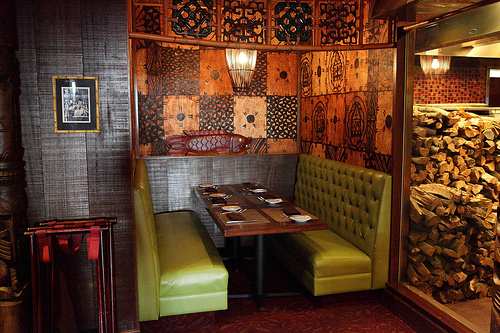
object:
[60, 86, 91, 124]
picture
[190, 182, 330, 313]
table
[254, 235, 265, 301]
pole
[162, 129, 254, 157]
fish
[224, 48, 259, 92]
light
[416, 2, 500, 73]
ceiling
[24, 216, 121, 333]
basket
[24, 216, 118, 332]
tray holder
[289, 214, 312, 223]
plate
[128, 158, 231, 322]
bench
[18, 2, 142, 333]
wall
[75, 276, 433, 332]
floor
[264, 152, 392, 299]
benches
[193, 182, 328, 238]
booth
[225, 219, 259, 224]
silverware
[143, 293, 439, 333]
carpet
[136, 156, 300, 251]
wall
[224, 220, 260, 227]
utensils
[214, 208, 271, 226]
placemat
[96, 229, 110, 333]
stands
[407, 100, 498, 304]
firewood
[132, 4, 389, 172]
wallpaper